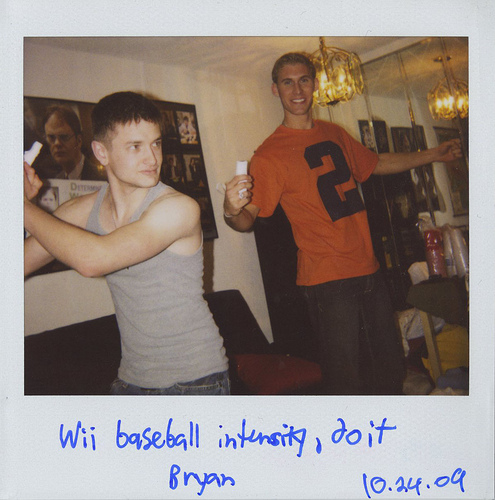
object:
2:
[302, 139, 370, 223]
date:
[363, 465, 472, 497]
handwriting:
[434, 468, 466, 490]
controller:
[221, 156, 255, 217]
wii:
[238, 183, 256, 209]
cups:
[409, 225, 449, 286]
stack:
[417, 211, 444, 244]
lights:
[309, 49, 368, 108]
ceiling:
[171, 40, 244, 85]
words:
[114, 418, 202, 452]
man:
[22, 88, 235, 397]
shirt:
[247, 119, 382, 288]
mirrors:
[386, 106, 456, 214]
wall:
[23, 45, 287, 343]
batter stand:
[23, 155, 205, 279]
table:
[396, 275, 471, 327]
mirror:
[358, 120, 430, 217]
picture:
[25, 35, 469, 398]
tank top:
[82, 182, 230, 390]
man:
[223, 52, 463, 394]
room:
[155, 35, 446, 133]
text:
[58, 417, 466, 499]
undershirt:
[114, 269, 230, 389]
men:
[23, 90, 232, 396]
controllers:
[22, 139, 256, 218]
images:
[172, 102, 211, 192]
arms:
[25, 191, 201, 280]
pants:
[298, 269, 409, 395]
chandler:
[421, 48, 470, 124]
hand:
[430, 137, 467, 165]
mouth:
[289, 97, 310, 104]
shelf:
[402, 275, 469, 388]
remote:
[234, 152, 249, 201]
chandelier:
[308, 34, 366, 108]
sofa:
[25, 288, 326, 398]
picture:
[23, 94, 99, 181]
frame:
[152, 97, 219, 241]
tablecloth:
[429, 301, 458, 318]